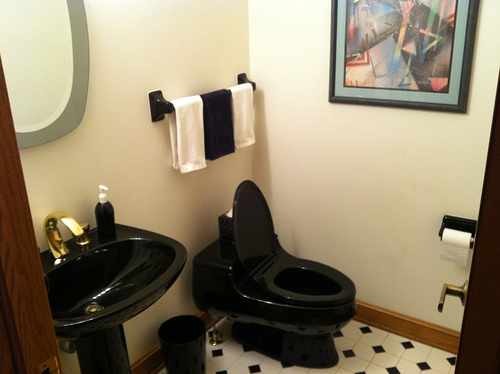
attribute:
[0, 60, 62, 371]
door jamb — brown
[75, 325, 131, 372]
sink base — black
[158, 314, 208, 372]
trash can — shiny, black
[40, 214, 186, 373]
sink — black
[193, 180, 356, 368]
toilet — shiny, black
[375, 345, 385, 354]
diamond — black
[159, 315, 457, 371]
floor — checkered, black, white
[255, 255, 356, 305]
toilet seat — black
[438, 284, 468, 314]
handle — gold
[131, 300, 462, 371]
base — brown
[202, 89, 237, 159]
towel — black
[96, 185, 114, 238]
soap dispenser — black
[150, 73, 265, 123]
towel rack — black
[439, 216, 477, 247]
toilet paper rack — black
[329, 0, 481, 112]
artwork — abstract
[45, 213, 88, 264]
faucet — gold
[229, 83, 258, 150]
towel — white